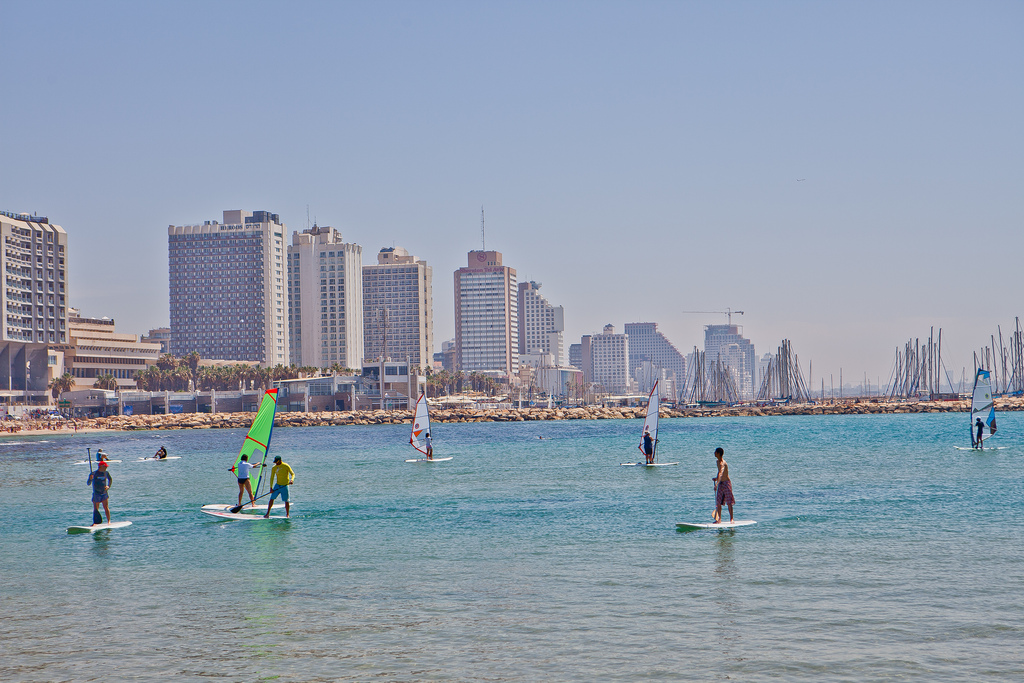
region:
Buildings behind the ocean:
[12, 171, 762, 397]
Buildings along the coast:
[6, 205, 668, 431]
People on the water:
[56, 383, 1021, 570]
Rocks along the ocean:
[88, 382, 959, 441]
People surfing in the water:
[54, 397, 855, 579]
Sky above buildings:
[12, 13, 1022, 257]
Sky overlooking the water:
[5, 7, 1020, 283]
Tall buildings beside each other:
[138, 183, 456, 376]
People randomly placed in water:
[72, 372, 1022, 554]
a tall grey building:
[146, 198, 298, 350]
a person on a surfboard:
[690, 437, 754, 513]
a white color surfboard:
[684, 493, 751, 539]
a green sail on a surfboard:
[228, 379, 295, 460]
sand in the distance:
[55, 385, 128, 446]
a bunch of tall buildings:
[810, 350, 912, 399]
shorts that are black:
[708, 476, 751, 496]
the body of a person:
[263, 470, 298, 505]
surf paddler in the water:
[672, 442, 772, 552]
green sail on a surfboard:
[223, 373, 289, 474]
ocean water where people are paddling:
[31, 557, 989, 671]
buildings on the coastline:
[158, 200, 448, 396]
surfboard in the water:
[671, 514, 758, 540]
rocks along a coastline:
[96, 406, 246, 442]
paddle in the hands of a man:
[222, 483, 279, 519]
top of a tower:
[462, 188, 505, 254]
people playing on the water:
[210, 391, 327, 560]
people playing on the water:
[64, 432, 131, 575]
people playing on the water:
[661, 411, 757, 574]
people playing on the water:
[953, 338, 1008, 542]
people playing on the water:
[590, 326, 680, 495]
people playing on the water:
[400, 388, 458, 469]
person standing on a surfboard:
[677, 444, 757, 537]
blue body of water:
[2, 412, 1023, 678]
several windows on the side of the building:
[457, 273, 515, 366]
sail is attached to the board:
[640, 379, 661, 471]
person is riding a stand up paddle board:
[67, 430, 143, 567]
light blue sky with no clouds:
[0, 1, 1023, 400]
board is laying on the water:
[675, 512, 767, 535]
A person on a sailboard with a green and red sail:
[191, 376, 299, 514]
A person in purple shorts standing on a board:
[681, 441, 768, 537]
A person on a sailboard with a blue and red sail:
[396, 384, 458, 465]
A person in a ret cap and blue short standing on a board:
[58, 440, 145, 542]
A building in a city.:
[164, 212, 289, 377]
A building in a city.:
[278, 226, 361, 369]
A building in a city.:
[363, 254, 428, 381]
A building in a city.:
[449, 245, 517, 383]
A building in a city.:
[514, 282, 566, 378]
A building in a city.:
[594, 326, 623, 384]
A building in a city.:
[620, 317, 660, 385]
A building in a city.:
[702, 320, 751, 397]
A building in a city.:
[69, 305, 167, 372]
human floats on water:
[674, 441, 754, 531]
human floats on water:
[219, 378, 274, 518]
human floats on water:
[260, 448, 296, 518]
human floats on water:
[147, 441, 180, 464]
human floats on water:
[390, 374, 452, 467]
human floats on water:
[941, 366, 998, 458]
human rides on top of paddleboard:
[709, 448, 738, 518]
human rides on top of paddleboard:
[71, 450, 136, 531]